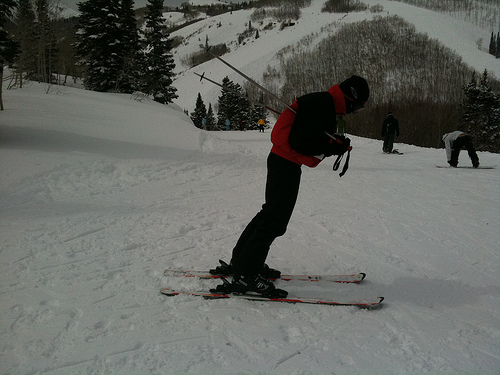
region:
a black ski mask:
[331, 73, 386, 126]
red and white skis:
[146, 271, 396, 307]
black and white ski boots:
[220, 253, 282, 308]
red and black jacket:
[208, 95, 355, 195]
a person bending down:
[395, 110, 485, 227]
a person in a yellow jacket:
[234, 107, 271, 144]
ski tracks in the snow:
[57, 183, 224, 365]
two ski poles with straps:
[223, 92, 368, 189]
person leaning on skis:
[150, 96, 384, 349]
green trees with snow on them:
[43, 5, 165, 108]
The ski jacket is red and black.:
[280, 92, 347, 179]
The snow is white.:
[67, 187, 151, 237]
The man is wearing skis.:
[156, 255, 441, 336]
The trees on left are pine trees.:
[81, 2, 180, 95]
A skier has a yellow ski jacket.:
[255, 115, 266, 127]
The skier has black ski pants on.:
[248, 133, 303, 283]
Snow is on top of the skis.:
[301, 267, 382, 289]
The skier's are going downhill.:
[217, 94, 466, 241]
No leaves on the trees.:
[343, 30, 456, 126]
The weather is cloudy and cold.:
[197, 39, 468, 304]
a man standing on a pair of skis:
[216, 76, 388, 312]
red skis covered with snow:
[156, 256, 384, 313]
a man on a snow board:
[435, 128, 490, 170]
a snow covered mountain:
[3, 65, 498, 347]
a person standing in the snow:
[378, 111, 402, 156]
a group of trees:
[67, 1, 170, 102]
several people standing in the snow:
[197, 111, 267, 134]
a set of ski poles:
[189, 37, 288, 124]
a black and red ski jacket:
[269, 83, 357, 173]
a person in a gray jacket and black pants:
[437, 128, 482, 168]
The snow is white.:
[25, 245, 135, 325]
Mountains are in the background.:
[0, 0, 495, 111]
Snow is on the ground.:
[19, 248, 126, 344]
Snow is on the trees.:
[68, 2, 186, 106]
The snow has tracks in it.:
[38, 230, 139, 368]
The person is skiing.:
[157, 64, 402, 336]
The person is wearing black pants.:
[192, 148, 324, 303]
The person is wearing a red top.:
[258, 77, 371, 182]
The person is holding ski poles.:
[171, 35, 383, 307]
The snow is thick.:
[29, 222, 140, 360]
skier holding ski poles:
[188, 40, 359, 212]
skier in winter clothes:
[171, 29, 376, 353]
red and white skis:
[137, 230, 394, 321]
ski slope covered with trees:
[280, 3, 452, 82]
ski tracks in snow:
[45, 210, 150, 306]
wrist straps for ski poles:
[330, 140, 370, 191]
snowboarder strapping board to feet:
[430, 122, 486, 179]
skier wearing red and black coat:
[260, 69, 375, 183]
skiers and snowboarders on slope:
[102, 88, 452, 329]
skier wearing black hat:
[270, 33, 392, 165]